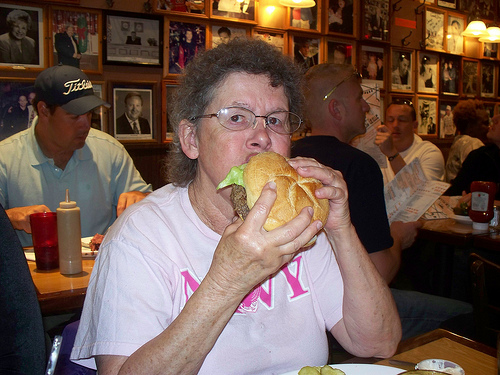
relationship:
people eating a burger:
[67, 35, 402, 375] [220, 147, 328, 239]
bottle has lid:
[54, 185, 85, 277] [56, 186, 79, 209]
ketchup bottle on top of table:
[467, 180, 494, 232] [413, 206, 498, 240]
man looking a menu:
[373, 88, 443, 170] [359, 108, 398, 165]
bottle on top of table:
[56, 189, 83, 275] [32, 204, 117, 302]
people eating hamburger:
[67, 35, 402, 375] [223, 145, 343, 255]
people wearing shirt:
[67, 35, 402, 375] [66, 172, 354, 374]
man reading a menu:
[287, 58, 485, 348] [374, 152, 453, 226]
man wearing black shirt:
[287, 58, 485, 348] [288, 130, 399, 257]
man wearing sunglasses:
[287, 58, 485, 348] [321, 65, 367, 98]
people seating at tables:
[9, 36, 497, 373] [17, 222, 492, 374]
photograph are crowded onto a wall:
[108, 75, 156, 148] [2, 0, 497, 207]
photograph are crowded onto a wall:
[387, 44, 414, 94] [2, 0, 497, 207]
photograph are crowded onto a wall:
[286, 29, 322, 74] [2, 0, 497, 207]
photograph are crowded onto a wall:
[46, 5, 107, 78] [2, 0, 497, 207]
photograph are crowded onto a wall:
[424, 6, 446, 60] [2, 0, 497, 207]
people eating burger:
[67, 35, 402, 375] [215, 151, 330, 248]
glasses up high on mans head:
[388, 100, 419, 110] [385, 97, 415, 144]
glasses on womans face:
[184, 106, 306, 138] [198, 70, 293, 200]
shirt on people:
[66, 172, 354, 374] [67, 35, 402, 375]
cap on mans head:
[33, 63, 111, 116] [32, 84, 114, 139]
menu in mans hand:
[392, 144, 452, 262] [382, 144, 480, 246]